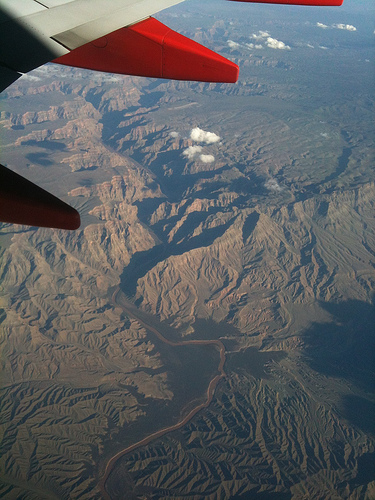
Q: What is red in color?
A: Engine.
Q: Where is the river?
A: Down below.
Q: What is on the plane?
A: Wing.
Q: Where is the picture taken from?
A: An airplane.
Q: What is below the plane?
A: Mountain range.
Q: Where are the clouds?
A: Above the mountains.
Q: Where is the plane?
A: In the sky.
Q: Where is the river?
A: Under the plane.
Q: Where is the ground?
A: Under the plane.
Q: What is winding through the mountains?
A: A river.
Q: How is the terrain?
A: Mountainous.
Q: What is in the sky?
A: Clouds.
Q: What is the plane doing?
A: Flying over the mountains.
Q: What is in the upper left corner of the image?
A: Wing.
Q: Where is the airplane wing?
A: Upper left corner.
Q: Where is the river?
A: In the valley.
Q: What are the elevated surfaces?
A: Mountains.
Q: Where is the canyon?
A: Running through middle of picture.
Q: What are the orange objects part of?
A: Airplane wing.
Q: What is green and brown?
A: Terrain.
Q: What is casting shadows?
A: Mountains.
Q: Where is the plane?
A: In the air.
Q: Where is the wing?
A: Over the engines.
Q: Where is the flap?
A: On the back of the wing.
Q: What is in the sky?
A: A plane.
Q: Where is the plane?
A: In the sky.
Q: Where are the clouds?
A: Under the plane.